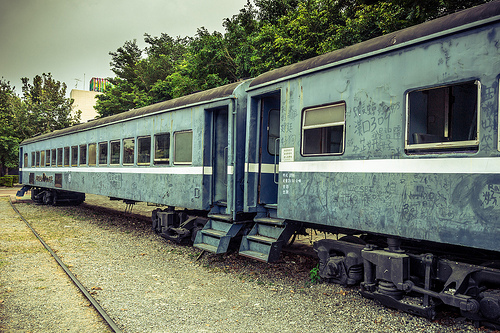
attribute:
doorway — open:
[196, 111, 236, 212]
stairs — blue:
[202, 211, 281, 261]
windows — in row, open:
[23, 142, 204, 165]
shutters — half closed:
[296, 95, 348, 127]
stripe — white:
[282, 153, 487, 203]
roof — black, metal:
[328, 45, 371, 71]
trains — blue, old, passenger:
[78, 106, 401, 247]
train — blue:
[251, 62, 499, 248]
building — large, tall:
[76, 78, 127, 106]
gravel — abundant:
[104, 240, 169, 299]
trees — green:
[250, 34, 318, 72]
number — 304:
[363, 102, 395, 141]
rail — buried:
[60, 270, 102, 309]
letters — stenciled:
[273, 176, 288, 190]